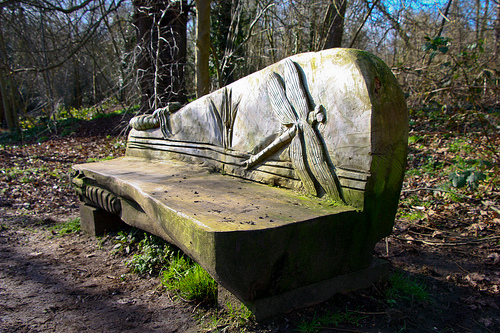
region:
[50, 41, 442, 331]
Stone bench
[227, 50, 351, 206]
dragonfly on stone bench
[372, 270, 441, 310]
patch of grass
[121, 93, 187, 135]
Bug on top of stone bench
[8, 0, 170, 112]
Leaf-less trees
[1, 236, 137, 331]
flat dirt covered ground.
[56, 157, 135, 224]
bug on front side of stone bench.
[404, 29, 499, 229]
Sparse looking bush.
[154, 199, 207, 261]
Discoloration on stone bench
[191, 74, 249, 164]
Tuft of grass on stone bench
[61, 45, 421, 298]
a large stone bench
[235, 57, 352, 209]
a dragonfly carved on the bench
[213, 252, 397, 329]
the leg of a bench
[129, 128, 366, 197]
grooves on the bench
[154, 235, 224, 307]
a patch of green grass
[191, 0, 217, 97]
the trunk of a tree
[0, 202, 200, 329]
a patch of brown mud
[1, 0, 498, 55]
a blue sky behind the trees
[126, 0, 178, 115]
the branches of a tree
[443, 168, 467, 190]
green leaves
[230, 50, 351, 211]
dragonfly carved on bench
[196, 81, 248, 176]
cattails carved on bench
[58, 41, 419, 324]
bench is stone bench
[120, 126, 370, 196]
paralell lines carved on bench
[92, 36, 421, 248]
moss has begun to grow on stone bench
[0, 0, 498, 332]
bench in natural wooded area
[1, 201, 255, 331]
mud on ground from recent rain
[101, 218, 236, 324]
grass+weeds beneath bench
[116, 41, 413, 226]
bench rises w/ the stone, is highest at edge nearest viewer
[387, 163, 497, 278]
fallen branches amid leaves on the ground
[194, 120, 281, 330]
a bench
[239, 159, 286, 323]
a bench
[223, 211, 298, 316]
a bench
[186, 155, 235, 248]
a bench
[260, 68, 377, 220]
dragonfly sculpture on rock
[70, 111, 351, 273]
bench is brown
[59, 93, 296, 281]
bench is made of stone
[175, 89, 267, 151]
grass on rock next to dragonfly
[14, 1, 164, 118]
tree is bare and brown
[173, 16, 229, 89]
tree has brown trunk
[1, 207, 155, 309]
ground is brown and bare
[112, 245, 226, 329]
clumps of grass near bench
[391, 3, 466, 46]
sky peeks through trees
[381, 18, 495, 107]
trees are leafless behind bench